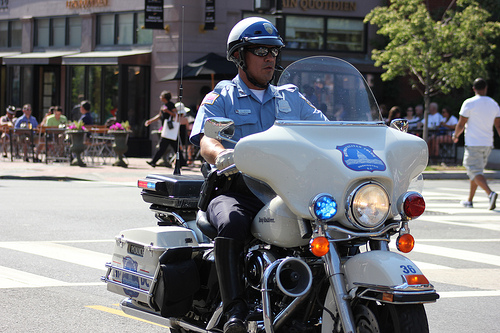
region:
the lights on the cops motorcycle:
[307, 166, 431, 262]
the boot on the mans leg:
[212, 232, 254, 329]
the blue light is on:
[309, 186, 339, 227]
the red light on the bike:
[400, 192, 426, 219]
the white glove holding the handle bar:
[212, 145, 242, 176]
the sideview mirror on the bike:
[199, 114, 246, 149]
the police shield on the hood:
[329, 131, 394, 183]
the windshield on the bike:
[276, 51, 392, 131]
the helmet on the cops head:
[213, 10, 287, 90]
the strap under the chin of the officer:
[233, 54, 280, 91]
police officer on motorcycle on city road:
[100, 13, 440, 326]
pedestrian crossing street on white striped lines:
[431, 70, 491, 225]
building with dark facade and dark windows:
[5, 0, 185, 156]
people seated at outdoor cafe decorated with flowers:
[0, 95, 130, 165]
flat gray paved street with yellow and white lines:
[0, 175, 492, 325]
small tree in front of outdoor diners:
[380, 5, 455, 160]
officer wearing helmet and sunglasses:
[221, 11, 283, 81]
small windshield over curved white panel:
[231, 57, 426, 222]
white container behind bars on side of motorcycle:
[105, 217, 196, 304]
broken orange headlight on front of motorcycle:
[301, 186, 432, 289]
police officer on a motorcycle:
[185, 13, 335, 278]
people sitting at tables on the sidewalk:
[7, 95, 131, 170]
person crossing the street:
[437, 62, 497, 193]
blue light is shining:
[310, 196, 339, 224]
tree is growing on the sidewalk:
[374, 6, 477, 173]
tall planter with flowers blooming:
[105, 114, 134, 171]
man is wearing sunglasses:
[245, 39, 280, 59]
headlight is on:
[346, 178, 393, 236]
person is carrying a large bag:
[156, 90, 182, 170]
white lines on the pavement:
[4, 223, 85, 300]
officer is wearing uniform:
[195, 21, 344, 266]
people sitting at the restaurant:
[11, 90, 120, 152]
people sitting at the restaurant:
[5, 97, 164, 178]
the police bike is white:
[81, 124, 433, 331]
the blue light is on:
[308, 187, 348, 224]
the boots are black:
[210, 240, 250, 330]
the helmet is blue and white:
[231, 19, 284, 46]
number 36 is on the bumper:
[396, 261, 417, 283]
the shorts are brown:
[456, 137, 498, 182]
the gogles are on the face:
[248, 48, 289, 62]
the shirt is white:
[456, 98, 498, 146]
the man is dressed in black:
[156, 100, 202, 162]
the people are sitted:
[16, 100, 143, 143]